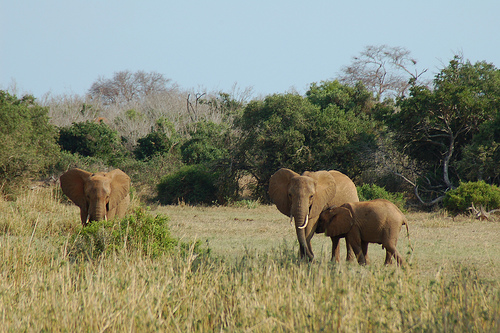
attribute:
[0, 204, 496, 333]
field — open, dry, green, brown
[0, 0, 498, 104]
sky — clear, pale, blue, dreary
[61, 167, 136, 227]
elephant — brown, powerful, nice size, mighty, herd, strong, big, near a mother, forward, standing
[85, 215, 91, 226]
tusk — white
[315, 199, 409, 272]
elephant — baby, nursing, young, a baby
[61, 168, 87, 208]
ear — large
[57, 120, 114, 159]
tree — green, lush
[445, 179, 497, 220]
bush — small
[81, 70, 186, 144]
tree — leafless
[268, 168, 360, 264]
elephant — mother, adult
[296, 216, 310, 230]
tusk — white, curled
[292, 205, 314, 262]
trunk — long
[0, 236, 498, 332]
grass — green, brown, tall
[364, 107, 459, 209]
tree — curved